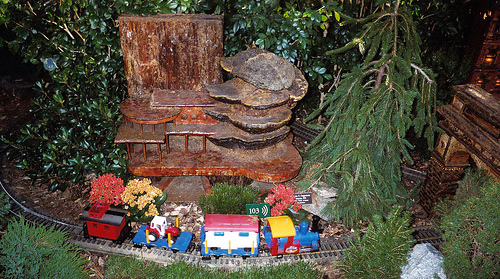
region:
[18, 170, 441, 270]
Train tracks through the bushes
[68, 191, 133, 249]
The caboose is red and black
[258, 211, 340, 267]
The engine has a black smoke stack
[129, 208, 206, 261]
Toy tractor on a train car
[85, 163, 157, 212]
Yellow and red flowers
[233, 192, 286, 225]
Green and white sign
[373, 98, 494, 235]
Tunnel made of wood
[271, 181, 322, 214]
Brown and white sign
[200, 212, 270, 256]
Train car has a red roof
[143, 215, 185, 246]
Tractor is red and white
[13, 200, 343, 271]
toy train on a train track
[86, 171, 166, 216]
pretty red and yellow flowers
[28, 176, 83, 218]
mulch on the ground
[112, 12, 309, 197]
wood crafting focal point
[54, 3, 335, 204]
wood crafted garden interest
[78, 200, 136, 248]
red caboose on back of toy train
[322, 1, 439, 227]
a bent tree branch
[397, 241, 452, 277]
a gray medium size rock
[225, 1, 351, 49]
green leaves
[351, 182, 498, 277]
two bushes with a gray rock in the middle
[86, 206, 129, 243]
red and black train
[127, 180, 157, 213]
yellow flowers in back of train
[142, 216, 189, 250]
toy tractor on the tracks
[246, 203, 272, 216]
green sign 103 saying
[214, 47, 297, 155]
four rocks foundation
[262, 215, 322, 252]
yellow blue red toy train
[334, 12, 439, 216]
green fir tree branches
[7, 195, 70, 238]
train tracks by grass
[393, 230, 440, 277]
white rock between two trees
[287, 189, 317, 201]
brown sign with words on it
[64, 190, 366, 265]
miniature train on the tracks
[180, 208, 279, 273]
white blue and red train car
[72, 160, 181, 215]
flowers in the train car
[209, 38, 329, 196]
wooden display in the middle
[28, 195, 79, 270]
mini train tracks on the ground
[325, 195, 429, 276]
small green tree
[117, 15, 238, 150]
brown tree trunk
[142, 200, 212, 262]
white tractor on the train car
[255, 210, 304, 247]
yellow rooftop of the car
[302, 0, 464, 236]
tall green tree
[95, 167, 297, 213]
flowers in the yard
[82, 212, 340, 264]
train decoration in the yard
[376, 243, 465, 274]
rock next to train track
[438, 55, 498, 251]
building the train goes in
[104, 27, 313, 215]
wood decoration for the yard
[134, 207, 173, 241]
train car carrying a tractor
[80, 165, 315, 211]
flowers are red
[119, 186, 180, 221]
flowers are yellow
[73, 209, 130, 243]
red and black train car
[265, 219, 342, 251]
engine is blue